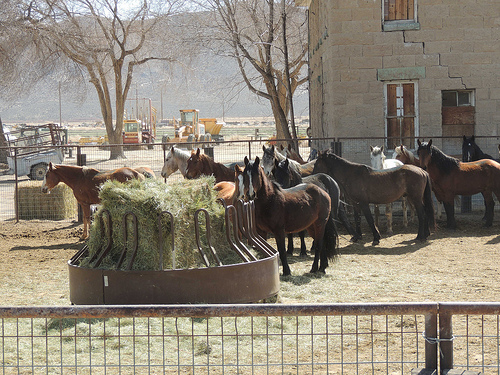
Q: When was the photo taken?
A: Daytime.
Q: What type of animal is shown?
A: Horses.